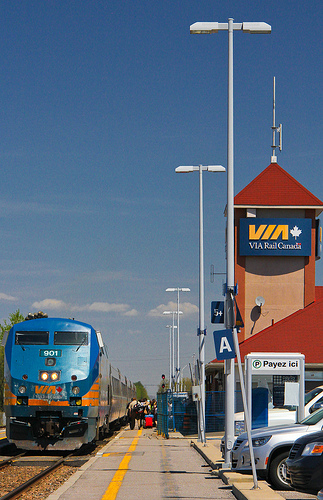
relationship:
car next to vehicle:
[233, 405, 321, 481] [286, 430, 321, 489]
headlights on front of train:
[189, 21, 270, 33] [4, 314, 137, 455]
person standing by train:
[130, 398, 135, 430] [4, 314, 137, 455]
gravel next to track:
[0, 463, 48, 496] [2, 475, 39, 499]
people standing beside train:
[128, 399, 140, 416] [4, 314, 137, 455]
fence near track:
[155, 388, 266, 438] [2, 475, 39, 499]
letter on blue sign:
[218, 335, 232, 354] [213, 329, 235, 361]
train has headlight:
[3, 309, 144, 460] [71, 384, 79, 395]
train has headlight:
[3, 309, 144, 460] [17, 385, 25, 394]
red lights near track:
[160, 371, 168, 388] [0, 412, 173, 496]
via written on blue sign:
[248, 221, 290, 241] [237, 217, 312, 257]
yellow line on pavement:
[97, 423, 146, 499] [42, 416, 243, 498]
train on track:
[3, 309, 144, 460] [0, 441, 93, 499]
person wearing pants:
[124, 394, 136, 429] [128, 411, 136, 433]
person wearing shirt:
[124, 394, 136, 429] [125, 400, 137, 411]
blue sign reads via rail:
[239, 218, 312, 257] [248, 241, 278, 250]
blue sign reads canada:
[239, 218, 312, 257] [277, 241, 302, 250]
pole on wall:
[164, 322, 179, 393] [212, 102, 224, 140]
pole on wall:
[161, 309, 183, 392] [212, 102, 224, 140]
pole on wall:
[164, 288, 192, 393] [212, 102, 224, 140]